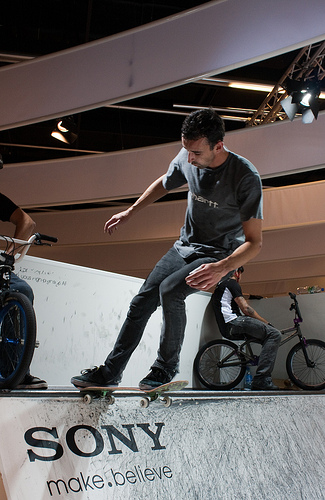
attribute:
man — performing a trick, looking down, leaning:
[71, 111, 265, 386]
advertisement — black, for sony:
[24, 419, 170, 497]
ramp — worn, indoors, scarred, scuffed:
[4, 388, 323, 499]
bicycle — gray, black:
[192, 293, 323, 389]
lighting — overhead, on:
[281, 77, 324, 124]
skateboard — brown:
[75, 379, 188, 409]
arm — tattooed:
[233, 293, 266, 325]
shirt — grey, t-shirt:
[161, 143, 262, 263]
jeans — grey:
[100, 250, 222, 377]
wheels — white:
[81, 391, 171, 408]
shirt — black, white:
[215, 276, 242, 328]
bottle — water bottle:
[295, 284, 324, 294]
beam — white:
[0, 1, 324, 131]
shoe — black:
[251, 377, 283, 391]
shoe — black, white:
[17, 372, 48, 389]